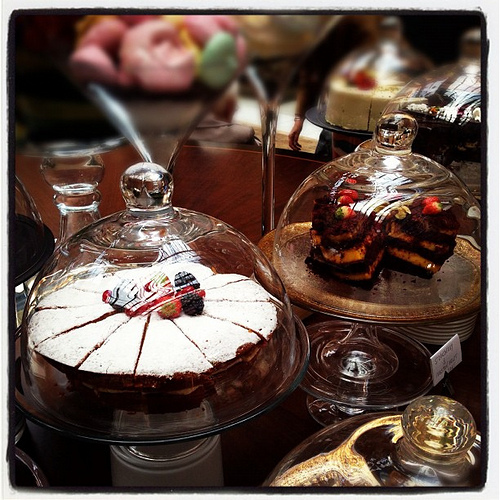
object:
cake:
[25, 256, 283, 414]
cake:
[305, 175, 464, 297]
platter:
[11, 298, 311, 446]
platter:
[256, 220, 485, 324]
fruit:
[99, 268, 206, 319]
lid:
[13, 160, 310, 474]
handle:
[117, 160, 175, 222]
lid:
[269, 107, 481, 311]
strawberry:
[423, 194, 443, 214]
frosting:
[29, 263, 277, 376]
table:
[10, 132, 480, 491]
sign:
[425, 333, 463, 386]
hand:
[288, 125, 302, 151]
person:
[288, 12, 384, 162]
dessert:
[65, 16, 249, 86]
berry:
[177, 290, 208, 318]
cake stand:
[253, 268, 491, 410]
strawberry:
[336, 194, 355, 206]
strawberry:
[335, 198, 361, 224]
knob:
[371, 110, 420, 157]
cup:
[75, 74, 235, 174]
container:
[317, 17, 436, 132]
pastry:
[321, 75, 410, 131]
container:
[384, 30, 484, 199]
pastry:
[397, 80, 481, 159]